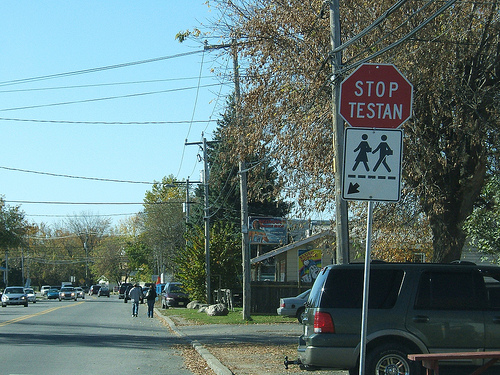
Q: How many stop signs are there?
A: One.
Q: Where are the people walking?
A: On the street.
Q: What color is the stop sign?
A: Red.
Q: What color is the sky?
A: Blue.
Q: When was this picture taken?
A: Daytime.